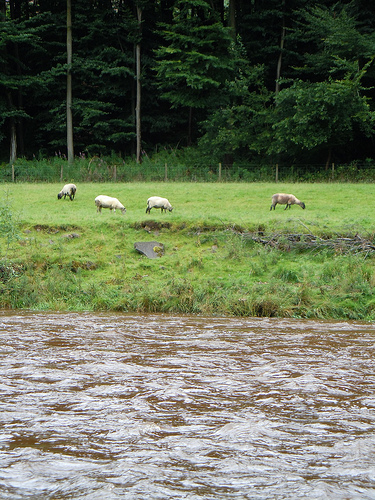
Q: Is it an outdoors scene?
A: Yes, it is outdoors.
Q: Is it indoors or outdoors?
A: It is outdoors.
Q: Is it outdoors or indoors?
A: It is outdoors.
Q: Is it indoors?
A: No, it is outdoors.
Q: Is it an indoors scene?
A: No, it is outdoors.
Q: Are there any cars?
A: No, there are no cars.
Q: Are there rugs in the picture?
A: No, there are no rugs.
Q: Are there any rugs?
A: No, there are no rugs.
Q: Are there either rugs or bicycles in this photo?
A: No, there are no rugs or bicycles.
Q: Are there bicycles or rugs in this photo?
A: No, there are no rugs or bicycles.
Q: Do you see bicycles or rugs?
A: No, there are no rugs or bicycles.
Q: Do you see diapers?
A: No, there are no diapers.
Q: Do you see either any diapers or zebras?
A: No, there are no diapers or zebras.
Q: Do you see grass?
A: Yes, there is grass.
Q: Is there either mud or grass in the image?
A: Yes, there is grass.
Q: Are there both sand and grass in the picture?
A: No, there is grass but no sand.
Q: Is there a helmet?
A: No, there are no helmets.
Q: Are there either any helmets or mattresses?
A: No, there are no helmets or mattresses.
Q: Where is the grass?
A: The grass is in the field.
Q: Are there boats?
A: No, there are no boats.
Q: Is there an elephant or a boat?
A: No, there are no boats or elephants.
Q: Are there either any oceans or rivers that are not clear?
A: No, there is a river but it is clear.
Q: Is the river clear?
A: Yes, the river is clear.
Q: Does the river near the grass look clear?
A: Yes, the river is clear.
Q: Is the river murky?
A: No, the river is clear.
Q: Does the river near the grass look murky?
A: No, the river is clear.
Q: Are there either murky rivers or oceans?
A: No, there is a river but it is clear.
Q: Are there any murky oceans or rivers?
A: No, there is a river but it is clear.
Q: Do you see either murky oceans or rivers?
A: No, there is a river but it is clear.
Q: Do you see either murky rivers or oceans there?
A: No, there is a river but it is clear.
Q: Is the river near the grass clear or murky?
A: The river is clear.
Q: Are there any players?
A: No, there are no players.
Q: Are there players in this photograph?
A: No, there are no players.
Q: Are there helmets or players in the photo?
A: No, there are no players or helmets.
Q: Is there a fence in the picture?
A: Yes, there is a fence.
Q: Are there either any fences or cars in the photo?
A: Yes, there is a fence.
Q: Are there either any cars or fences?
A: Yes, there is a fence.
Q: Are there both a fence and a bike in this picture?
A: No, there is a fence but no bikes.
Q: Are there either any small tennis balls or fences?
A: Yes, there is a small fence.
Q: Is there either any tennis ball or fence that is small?
A: Yes, the fence is small.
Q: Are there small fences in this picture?
A: Yes, there is a small fence.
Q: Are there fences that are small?
A: Yes, there is a fence that is small.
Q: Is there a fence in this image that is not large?
A: Yes, there is a small fence.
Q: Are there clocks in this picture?
A: No, there are no clocks.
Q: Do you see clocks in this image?
A: No, there are no clocks.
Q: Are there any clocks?
A: No, there are no clocks.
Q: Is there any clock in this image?
A: No, there are no clocks.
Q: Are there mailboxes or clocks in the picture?
A: No, there are no clocks or mailboxes.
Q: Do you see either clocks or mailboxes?
A: No, there are no clocks or mailboxes.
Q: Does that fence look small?
A: Yes, the fence is small.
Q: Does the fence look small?
A: Yes, the fence is small.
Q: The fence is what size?
A: The fence is small.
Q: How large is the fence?
A: The fence is small.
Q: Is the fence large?
A: No, the fence is small.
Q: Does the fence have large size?
A: No, the fence is small.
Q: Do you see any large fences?
A: No, there is a fence but it is small.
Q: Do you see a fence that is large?
A: No, there is a fence but it is small.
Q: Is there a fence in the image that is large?
A: No, there is a fence but it is small.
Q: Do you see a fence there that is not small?
A: No, there is a fence but it is small.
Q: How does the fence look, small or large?
A: The fence is small.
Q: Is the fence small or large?
A: The fence is small.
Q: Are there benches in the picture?
A: No, there are no benches.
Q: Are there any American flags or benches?
A: No, there are no benches or American flags.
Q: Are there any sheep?
A: Yes, there is a sheep.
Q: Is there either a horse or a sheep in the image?
A: Yes, there is a sheep.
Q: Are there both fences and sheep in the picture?
A: Yes, there are both a sheep and a fence.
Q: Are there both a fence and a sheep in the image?
A: Yes, there are both a sheep and a fence.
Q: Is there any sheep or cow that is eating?
A: Yes, the sheep is eating.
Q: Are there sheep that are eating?
A: Yes, there is a sheep that is eating.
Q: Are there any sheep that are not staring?
A: Yes, there is a sheep that is eating.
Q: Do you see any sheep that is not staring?
A: Yes, there is a sheep that is eating .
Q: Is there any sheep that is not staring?
A: Yes, there is a sheep that is eating.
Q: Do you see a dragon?
A: No, there are no dragons.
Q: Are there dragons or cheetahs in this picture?
A: No, there are no dragons or cheetahs.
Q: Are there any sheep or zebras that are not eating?
A: No, there is a sheep but it is eating.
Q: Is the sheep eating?
A: Yes, the sheep is eating.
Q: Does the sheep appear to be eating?
A: Yes, the sheep is eating.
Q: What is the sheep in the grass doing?
A: The sheep is eating.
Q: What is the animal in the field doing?
A: The sheep is eating.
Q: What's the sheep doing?
A: The sheep is eating.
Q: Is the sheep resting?
A: No, the sheep is eating.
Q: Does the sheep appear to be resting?
A: No, the sheep is eating.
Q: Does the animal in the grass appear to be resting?
A: No, the sheep is eating.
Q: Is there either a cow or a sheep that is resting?
A: No, there is a sheep but it is eating.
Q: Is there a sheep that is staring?
A: No, there is a sheep but it is eating.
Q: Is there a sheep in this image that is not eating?
A: No, there is a sheep but it is eating.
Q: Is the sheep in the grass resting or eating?
A: The sheep is eating.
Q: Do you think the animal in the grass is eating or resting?
A: The sheep is eating.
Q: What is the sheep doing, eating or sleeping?
A: The sheep is eating.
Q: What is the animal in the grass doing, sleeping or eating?
A: The sheep is eating.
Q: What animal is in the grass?
A: The animal is a sheep.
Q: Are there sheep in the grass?
A: Yes, there is a sheep in the grass.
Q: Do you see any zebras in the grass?
A: No, there is a sheep in the grass.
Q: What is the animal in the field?
A: The animal is a sheep.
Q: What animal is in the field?
A: The animal is a sheep.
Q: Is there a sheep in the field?
A: Yes, there is a sheep in the field.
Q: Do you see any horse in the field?
A: No, there is a sheep in the field.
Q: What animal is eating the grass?
A: The sheep is eating the grass.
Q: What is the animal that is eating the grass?
A: The animal is a sheep.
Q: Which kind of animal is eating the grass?
A: The animal is a sheep.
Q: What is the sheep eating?
A: The sheep is eating grass.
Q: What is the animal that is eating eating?
A: The sheep is eating grass.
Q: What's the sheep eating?
A: The sheep is eating grass.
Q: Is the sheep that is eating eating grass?
A: Yes, the sheep is eating grass.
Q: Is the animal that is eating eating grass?
A: Yes, the sheep is eating grass.